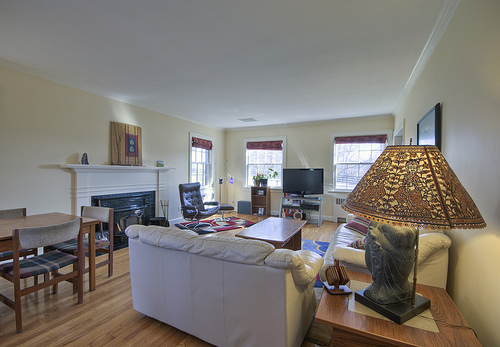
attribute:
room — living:
[3, 84, 483, 338]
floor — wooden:
[1, 212, 351, 345]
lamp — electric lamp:
[307, 160, 457, 335]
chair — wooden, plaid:
[6, 217, 89, 332]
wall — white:
[183, 87, 464, 244]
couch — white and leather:
[318, 209, 447, 291]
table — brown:
[314, 262, 480, 345]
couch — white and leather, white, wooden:
[118, 217, 318, 345]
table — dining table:
[15, 206, 102, 247]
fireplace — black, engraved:
[88, 189, 155, 249]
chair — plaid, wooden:
[76, 207, 114, 294]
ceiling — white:
[4, 0, 457, 128]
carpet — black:
[193, 202, 270, 243]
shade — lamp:
[358, 173, 468, 320]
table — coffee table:
[237, 211, 314, 250]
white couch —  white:
[119, 232, 317, 345]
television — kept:
[278, 165, 327, 197]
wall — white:
[8, 96, 103, 147]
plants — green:
[249, 166, 280, 186]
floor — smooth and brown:
[18, 180, 380, 340]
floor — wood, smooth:
[3, 241, 229, 344]